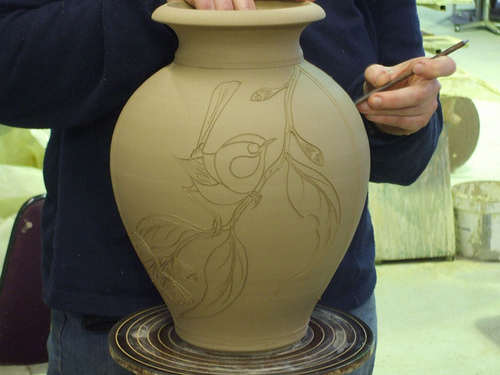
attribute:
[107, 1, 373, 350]
vase — wet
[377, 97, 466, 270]
table — wooden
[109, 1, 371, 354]
tan vase — ceramic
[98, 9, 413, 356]
pot — large, ceramic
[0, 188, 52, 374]
chair — vinyl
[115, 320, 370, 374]
pottery wheel — dirty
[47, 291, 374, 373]
jeans — blue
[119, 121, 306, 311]
branch — long